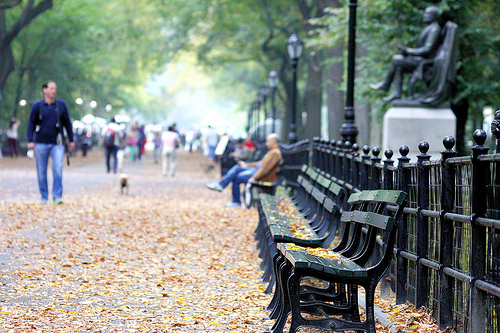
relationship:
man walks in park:
[21, 69, 88, 231] [2, 3, 498, 328]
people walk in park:
[54, 97, 241, 199] [4, 60, 319, 288]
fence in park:
[278, 127, 498, 332] [2, 3, 498, 328]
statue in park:
[381, 30, 479, 112] [2, 3, 498, 328]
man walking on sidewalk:
[24, 79, 76, 207] [0, 142, 498, 330]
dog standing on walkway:
[119, 171, 130, 198] [2, 148, 280, 328]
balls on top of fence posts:
[362, 127, 487, 158] [393, 143, 498, 330]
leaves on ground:
[2, 155, 442, 329] [445, 148, 473, 188]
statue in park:
[372, 3, 470, 109] [2, 3, 498, 328]